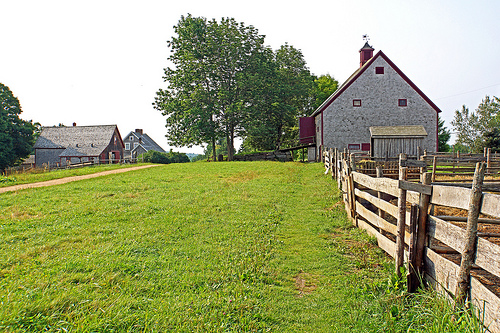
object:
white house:
[297, 33, 442, 163]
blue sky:
[0, 0, 499, 155]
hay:
[390, 175, 498, 230]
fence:
[320, 146, 498, 331]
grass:
[0, 160, 499, 332]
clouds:
[0, 0, 499, 155]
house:
[121, 128, 164, 162]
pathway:
[0, 163, 166, 194]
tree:
[0, 83, 33, 177]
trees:
[149, 12, 308, 161]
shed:
[365, 125, 427, 157]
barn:
[310, 41, 441, 160]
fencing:
[315, 139, 492, 302]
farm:
[0, 162, 498, 332]